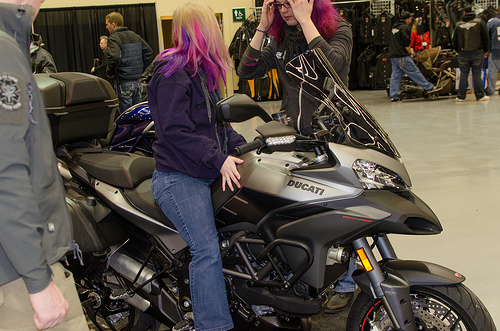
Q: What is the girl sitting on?
A: Motorcycle.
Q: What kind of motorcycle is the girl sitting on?
A: Ducati.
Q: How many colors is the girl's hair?
A: Three.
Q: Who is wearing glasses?
A: Girl.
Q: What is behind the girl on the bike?
A: Helmet.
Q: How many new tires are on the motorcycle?
A: Two.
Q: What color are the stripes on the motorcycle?
A: Red.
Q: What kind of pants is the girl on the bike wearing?
A: Jeans.